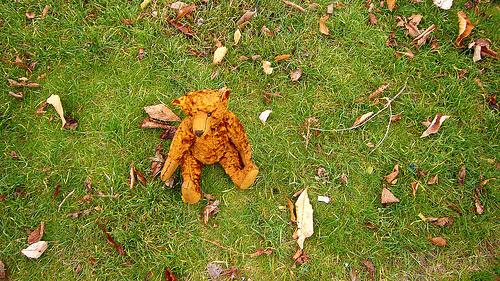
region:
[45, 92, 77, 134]
leaf laying on green grass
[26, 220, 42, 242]
leaf laying on green grass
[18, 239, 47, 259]
leaf laying on green grass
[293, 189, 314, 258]
leaf laying on green grass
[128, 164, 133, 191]
leaf laying on green grass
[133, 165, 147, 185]
leaf laying on green grass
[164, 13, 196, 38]
leaf laying on green grass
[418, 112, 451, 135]
leaf laying on green grass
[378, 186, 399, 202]
leaf laying on green grass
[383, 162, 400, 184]
leaf laying on green grass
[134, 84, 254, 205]
this is a teddy bear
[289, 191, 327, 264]
this is a dry leaf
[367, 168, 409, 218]
this is a dry leaf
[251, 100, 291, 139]
this is a dry leaf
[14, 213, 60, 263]
this is a dry leaf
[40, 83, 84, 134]
this is a dry leaf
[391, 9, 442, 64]
this is a dry leaf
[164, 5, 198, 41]
this is a dry leaf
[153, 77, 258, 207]
a brown teddy bear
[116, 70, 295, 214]
a teddy bear in the grass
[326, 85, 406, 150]
a stick on the grass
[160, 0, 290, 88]
leaves on the grass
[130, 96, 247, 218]
a teddy bear sitting next to leave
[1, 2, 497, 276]
grass with leaves on it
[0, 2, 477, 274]
green and brown grass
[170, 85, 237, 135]
the head of the teddy bear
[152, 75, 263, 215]
a teddy bear sitting on the ground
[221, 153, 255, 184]
the leg of the teddy bear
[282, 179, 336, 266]
Small brown leaf on the green grass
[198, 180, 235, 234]
Small brown leaf on the green grass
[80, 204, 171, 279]
Small brown leaf on the green grass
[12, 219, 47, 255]
Small brown leaf on the green grass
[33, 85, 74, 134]
Small brown leaf on the green grass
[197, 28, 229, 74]
Small brown leaf on the green grass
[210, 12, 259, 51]
Small brown leaf on the green grass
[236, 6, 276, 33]
Small brown leaf on the green grass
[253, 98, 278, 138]
Small brown leaf on the green grass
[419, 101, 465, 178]
Small brown leaf on the green grass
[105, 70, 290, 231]
this is a teddy bear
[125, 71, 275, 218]
teddy bear sitting on the ground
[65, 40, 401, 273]
the ground is grassy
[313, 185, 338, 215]
white debris in grass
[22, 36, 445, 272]
brown leafs on ground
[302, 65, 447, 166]
brown twigs on ground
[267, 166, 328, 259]
light tan leaf on ground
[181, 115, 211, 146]
black nose on bearq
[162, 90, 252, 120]
ears on the bear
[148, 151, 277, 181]
paws on the ground